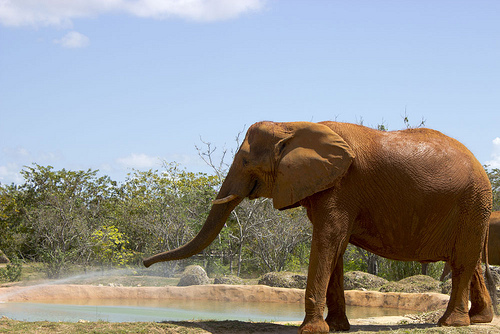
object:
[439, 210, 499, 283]
elephant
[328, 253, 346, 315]
leg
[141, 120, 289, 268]
head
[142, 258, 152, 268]
nose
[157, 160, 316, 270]
bush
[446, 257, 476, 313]
leg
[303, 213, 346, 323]
leg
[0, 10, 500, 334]
nature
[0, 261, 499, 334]
land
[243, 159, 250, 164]
eye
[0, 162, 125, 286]
branches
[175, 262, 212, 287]
rock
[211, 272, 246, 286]
rock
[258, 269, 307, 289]
rock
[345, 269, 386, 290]
rock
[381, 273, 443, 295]
rock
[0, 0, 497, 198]
sky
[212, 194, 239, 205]
tusk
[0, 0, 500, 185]
clouds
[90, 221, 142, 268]
bush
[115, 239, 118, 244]
foliage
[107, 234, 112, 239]
foliage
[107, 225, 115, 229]
foliage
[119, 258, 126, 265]
foliage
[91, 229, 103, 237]
foliage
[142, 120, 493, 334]
elephant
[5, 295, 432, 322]
water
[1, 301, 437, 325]
creek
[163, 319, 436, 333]
shadow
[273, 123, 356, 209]
ear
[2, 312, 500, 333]
grass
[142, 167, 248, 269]
trunk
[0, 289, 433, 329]
hole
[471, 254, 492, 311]
legs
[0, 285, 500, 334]
path